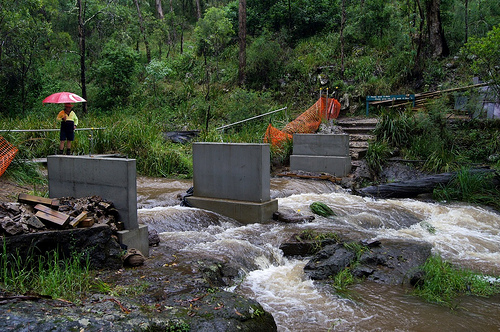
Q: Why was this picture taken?
A: Showing destruction.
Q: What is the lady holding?
A: Umbrella.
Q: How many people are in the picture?
A: One.